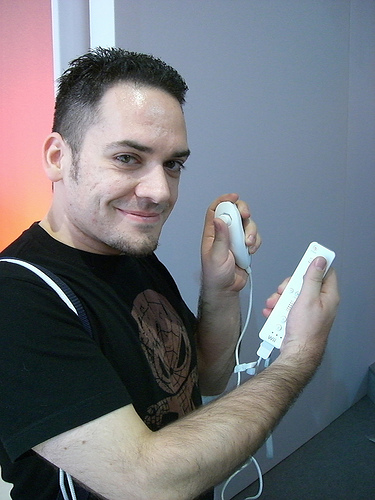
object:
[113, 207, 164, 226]
lips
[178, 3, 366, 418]
wall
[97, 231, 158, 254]
beard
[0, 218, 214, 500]
shirt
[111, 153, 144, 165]
eye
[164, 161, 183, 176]
eye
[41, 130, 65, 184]
ear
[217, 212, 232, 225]
button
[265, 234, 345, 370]
remote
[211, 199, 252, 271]
controllers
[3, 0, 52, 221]
wall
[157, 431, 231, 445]
hair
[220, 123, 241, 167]
ground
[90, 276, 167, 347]
tee shirt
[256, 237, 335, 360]
controller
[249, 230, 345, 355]
vegetable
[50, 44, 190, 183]
black hair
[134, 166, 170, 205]
nose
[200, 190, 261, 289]
hand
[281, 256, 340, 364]
hand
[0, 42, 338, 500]
man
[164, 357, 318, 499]
arm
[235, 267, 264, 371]
cord